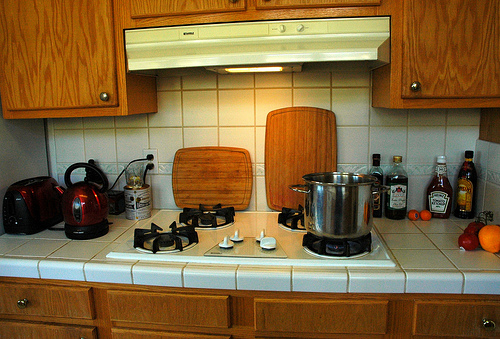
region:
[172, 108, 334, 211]
two wooden cutting board on a kitchen counter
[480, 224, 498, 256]
an orange on a kitchen counter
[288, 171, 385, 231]
a stainless steel pot on a burner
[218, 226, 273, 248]
white knobs on top of a burner surface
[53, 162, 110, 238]
a red and black kettle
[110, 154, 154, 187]
black plugs and wires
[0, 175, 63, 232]
a red and black toaster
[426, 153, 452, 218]
a bottle of ketchup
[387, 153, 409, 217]
a bottle of oil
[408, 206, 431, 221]
two clementines on a kitchen counter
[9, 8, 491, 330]
Photo taken in a kitchen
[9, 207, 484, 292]
Kitchen counter is white tile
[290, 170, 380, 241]
Silver pot on the stove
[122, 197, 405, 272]
Gas stove top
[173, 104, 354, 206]
Cutting boards behind the stove top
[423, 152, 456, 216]
Bottle of ketchup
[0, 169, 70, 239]
Red and black toaster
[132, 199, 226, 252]
Stove burners are black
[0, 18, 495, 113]
Cabinets made of wood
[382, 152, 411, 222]
Olive oil on the counter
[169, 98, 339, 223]
Cutting boards standing against the wall.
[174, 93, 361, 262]
Cuttingboards behind a stove.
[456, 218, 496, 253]
An orange sits next to a tomato.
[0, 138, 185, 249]
Applainces are plugged into the wall.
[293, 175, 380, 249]
A pot is on the stove.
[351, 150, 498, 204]
Bottles are on the counter.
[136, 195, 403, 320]
A stove is on top of the counter.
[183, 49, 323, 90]
A range lights above the stove.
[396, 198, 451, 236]
Two tangerines are between bottles.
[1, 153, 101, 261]
A tea kettle sits next to the toaster.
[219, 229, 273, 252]
The knobs on the stove.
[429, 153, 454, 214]
The bottle of ketchup on the counter.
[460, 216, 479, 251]
The apples on the counter.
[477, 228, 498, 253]
The orange on the counter.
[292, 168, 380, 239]
The pot on the stove.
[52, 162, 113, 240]
The tea kettle on the counter.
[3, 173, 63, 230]
The toaster on the counter.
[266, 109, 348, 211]
The cutting board on the right.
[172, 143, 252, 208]
The cutting board on the left.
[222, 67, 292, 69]
The light above the stove.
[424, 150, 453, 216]
A red ketchup bottle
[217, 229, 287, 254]
The knobs for the stove burners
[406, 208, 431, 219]
The two small oranges near the ketchup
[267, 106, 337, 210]
The vertically placed cutting board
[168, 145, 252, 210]
The horizontal cutting board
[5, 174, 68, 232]
The red toaster on the counter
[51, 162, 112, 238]
The red tea pot next to the oven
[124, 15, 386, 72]
The hood vent above the stove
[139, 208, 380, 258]
The four burners on the stove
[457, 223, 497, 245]
The pile of oranges and tomatoes